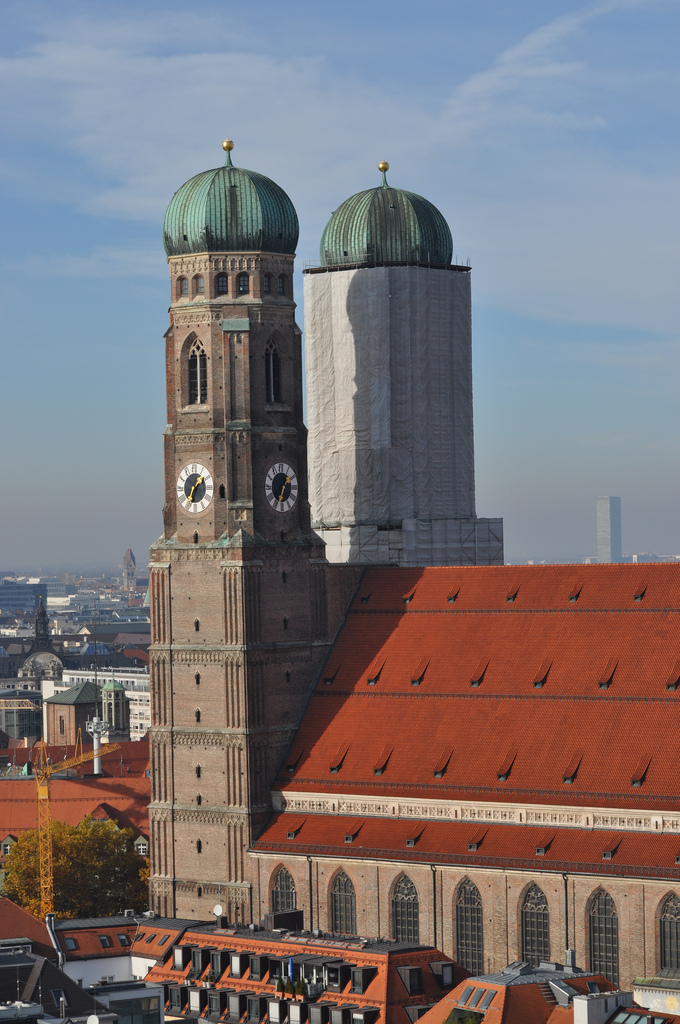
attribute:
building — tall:
[162, 131, 678, 985]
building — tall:
[304, 160, 509, 563]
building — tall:
[595, 490, 632, 561]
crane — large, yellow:
[23, 729, 129, 929]